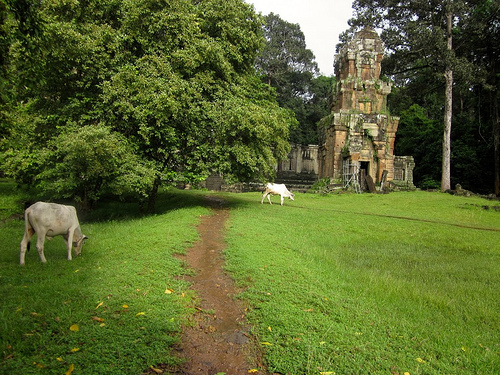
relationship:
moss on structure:
[362, 127, 381, 162] [193, 20, 418, 198]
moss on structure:
[373, 79, 382, 93] [193, 20, 418, 198]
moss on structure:
[318, 111, 352, 132] [193, 20, 418, 198]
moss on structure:
[377, 105, 398, 126] [193, 20, 418, 198]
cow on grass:
[16, 200, 89, 268] [1, 179, 499, 374]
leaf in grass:
[163, 285, 174, 301] [1, 179, 499, 374]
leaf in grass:
[67, 323, 83, 334] [1, 179, 499, 374]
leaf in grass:
[68, 345, 85, 356] [1, 179, 499, 374]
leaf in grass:
[63, 360, 76, 374] [1, 179, 499, 374]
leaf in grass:
[122, 302, 133, 313] [1, 179, 499, 374]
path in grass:
[154, 191, 274, 374] [1, 179, 499, 374]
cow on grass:
[260, 184, 295, 209] [1, 179, 499, 374]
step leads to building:
[289, 187, 322, 197] [276, 139, 321, 175]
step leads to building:
[282, 181, 317, 190] [276, 139, 321, 175]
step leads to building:
[276, 177, 316, 186] [276, 139, 321, 175]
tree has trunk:
[359, 2, 497, 199] [439, 9, 455, 197]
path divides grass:
[154, 191, 274, 374] [1, 179, 499, 374]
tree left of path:
[0, 0, 300, 207] [154, 191, 274, 374]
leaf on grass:
[163, 285, 174, 301] [1, 179, 499, 374]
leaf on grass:
[122, 302, 133, 313] [1, 179, 499, 374]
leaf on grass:
[67, 323, 83, 334] [1, 179, 499, 374]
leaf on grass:
[68, 345, 85, 356] [1, 179, 499, 374]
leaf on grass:
[63, 360, 76, 374] [1, 179, 499, 374]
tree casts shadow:
[0, 0, 300, 207] [17, 187, 252, 228]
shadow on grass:
[218, 196, 499, 234] [1, 179, 499, 374]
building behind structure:
[276, 139, 321, 175] [193, 20, 418, 198]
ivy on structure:
[381, 105, 396, 133] [193, 20, 418, 198]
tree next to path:
[0, 0, 300, 207] [154, 191, 274, 374]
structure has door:
[193, 20, 418, 198] [358, 156, 370, 191]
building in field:
[276, 139, 321, 175] [2, 184, 498, 374]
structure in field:
[193, 20, 418, 198] [2, 184, 498, 374]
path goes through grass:
[154, 191, 274, 374] [1, 179, 499, 374]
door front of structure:
[358, 156, 370, 191] [193, 20, 418, 198]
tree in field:
[359, 2, 497, 199] [2, 184, 498, 374]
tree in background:
[359, 2, 497, 199] [186, 60, 498, 197]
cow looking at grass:
[16, 200, 89, 268] [1, 179, 499, 374]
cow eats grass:
[16, 200, 89, 268] [1, 179, 499, 374]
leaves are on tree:
[456, 0, 498, 40] [359, 2, 497, 199]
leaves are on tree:
[439, 45, 479, 88] [359, 2, 497, 199]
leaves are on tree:
[349, 0, 409, 16] [359, 2, 497, 199]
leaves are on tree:
[383, 44, 437, 76] [359, 2, 497, 199]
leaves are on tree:
[470, 70, 498, 93] [359, 2, 497, 199]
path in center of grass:
[154, 191, 274, 374] [1, 179, 499, 374]